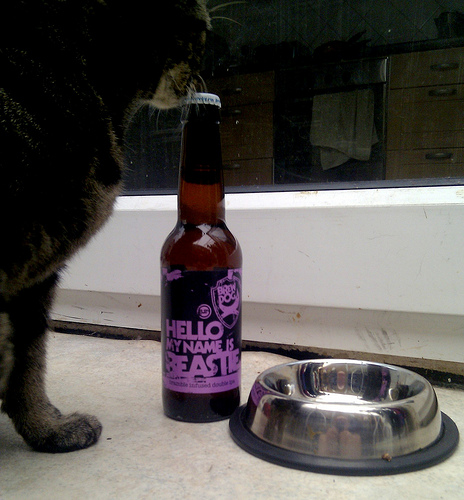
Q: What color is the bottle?
A: Brown.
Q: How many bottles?
A: One.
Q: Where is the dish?
A: To the right of the bottle.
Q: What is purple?
A: Lettering on the bottle.